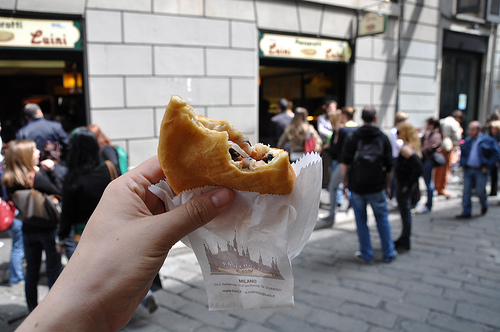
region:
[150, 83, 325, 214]
half eaten empanada held by a person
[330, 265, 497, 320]
grey cobblestone street where people are walking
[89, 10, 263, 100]
concrete building in the background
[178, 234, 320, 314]
white paper bag where the food was packaged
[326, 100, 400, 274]
man standing on street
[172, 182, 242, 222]
thumb of a person holding food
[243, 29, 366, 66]
overhead sign of a business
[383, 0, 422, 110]
shadow casted on the building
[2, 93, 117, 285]
crowd of people entering restaurant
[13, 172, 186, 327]
left hand of person holding food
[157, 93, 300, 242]
Food in the hand of a person standing in the street.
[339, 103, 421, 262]
A man with a backpack and a blonde haired woman standing in the road.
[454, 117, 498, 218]
A balding man walking up the street with a blue coat on.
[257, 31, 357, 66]
Sign hanging in the middle doorway.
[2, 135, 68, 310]
Girl with light brown hair to the left of the hand.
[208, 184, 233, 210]
Up close of a thumb nail.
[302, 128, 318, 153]
Red bag on a woman's right side back.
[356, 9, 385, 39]
Smaller sign hanging above a middle doorway.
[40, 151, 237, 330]
Left hand of a person holding food.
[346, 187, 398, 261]
Blue jeans on a man facing away from the camera.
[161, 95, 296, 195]
partially eaten pizza pocket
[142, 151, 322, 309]
pizza pocket paper wrapper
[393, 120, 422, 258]
girl in black with bare shoulders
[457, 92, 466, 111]
small blue sign on black door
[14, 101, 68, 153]
tall balding man in black coat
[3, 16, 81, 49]
partial sign on the left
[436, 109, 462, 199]
man wearing orange pants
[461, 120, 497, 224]
bald man in blue walking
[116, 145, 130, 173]
green backpack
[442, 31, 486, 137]
black glass door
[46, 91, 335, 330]
A person is holding food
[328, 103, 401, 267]
Person is wearing blue jeans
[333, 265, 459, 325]
The street is made out of gray brick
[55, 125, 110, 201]
Woman has long dark hair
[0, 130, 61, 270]
Woman has long brown hair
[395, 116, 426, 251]
Woman has blonde hair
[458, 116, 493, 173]
Person is wearing a blue jacket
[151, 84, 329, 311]
Food is in a small white bag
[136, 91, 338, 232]
Food was bitten into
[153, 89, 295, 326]
Food is in a white bag.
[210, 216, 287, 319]
Logo on side of white bag.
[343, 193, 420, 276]
Person wearing blue jeans.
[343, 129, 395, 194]
Person wearing dark shirt.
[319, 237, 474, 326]
Street is made of bricks.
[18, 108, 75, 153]
Person is wearing dark coat.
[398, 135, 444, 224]
Person wearing dark shirt.